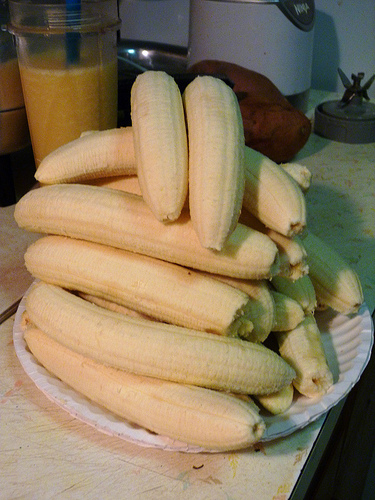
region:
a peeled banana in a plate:
[9, 190, 279, 279]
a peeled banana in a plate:
[26, 293, 298, 398]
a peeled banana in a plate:
[26, 329, 271, 458]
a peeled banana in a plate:
[22, 241, 258, 335]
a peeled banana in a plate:
[123, 66, 183, 222]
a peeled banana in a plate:
[177, 67, 253, 252]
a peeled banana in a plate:
[307, 225, 362, 321]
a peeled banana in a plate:
[285, 322, 355, 407]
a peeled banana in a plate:
[96, 163, 214, 216]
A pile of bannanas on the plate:
[30, 69, 364, 458]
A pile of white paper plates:
[305, 308, 374, 451]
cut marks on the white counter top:
[2, 423, 97, 499]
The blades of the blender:
[308, 56, 373, 144]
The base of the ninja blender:
[182, 0, 319, 88]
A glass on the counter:
[8, 0, 126, 187]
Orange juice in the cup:
[19, 0, 118, 130]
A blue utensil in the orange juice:
[61, 0, 85, 66]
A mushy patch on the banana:
[302, 321, 328, 371]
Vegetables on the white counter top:
[187, 49, 313, 161]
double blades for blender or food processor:
[315, 67, 374, 141]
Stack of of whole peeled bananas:
[21, 77, 361, 326]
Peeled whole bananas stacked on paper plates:
[21, 72, 374, 456]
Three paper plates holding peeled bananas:
[15, 265, 373, 452]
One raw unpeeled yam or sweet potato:
[185, 59, 311, 165]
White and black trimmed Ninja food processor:
[186, 1, 312, 111]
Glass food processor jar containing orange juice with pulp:
[5, 3, 121, 179]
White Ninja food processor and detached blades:
[187, 0, 373, 141]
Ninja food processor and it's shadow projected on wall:
[242, 0, 344, 98]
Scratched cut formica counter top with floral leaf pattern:
[52, 454, 282, 499]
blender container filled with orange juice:
[1, 0, 119, 181]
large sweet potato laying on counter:
[187, 57, 308, 162]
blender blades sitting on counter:
[316, 67, 373, 137]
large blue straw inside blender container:
[66, 0, 81, 64]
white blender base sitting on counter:
[188, 1, 312, 111]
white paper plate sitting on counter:
[16, 237, 372, 438]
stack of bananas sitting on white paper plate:
[17, 69, 363, 441]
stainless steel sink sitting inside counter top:
[0, 31, 191, 223]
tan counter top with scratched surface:
[0, 92, 372, 497]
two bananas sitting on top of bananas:
[126, 69, 248, 256]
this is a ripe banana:
[178, 74, 262, 260]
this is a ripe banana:
[131, 67, 186, 223]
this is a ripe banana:
[28, 332, 268, 460]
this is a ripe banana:
[24, 290, 299, 396]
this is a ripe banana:
[24, 246, 254, 340]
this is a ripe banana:
[11, 195, 293, 288]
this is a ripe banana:
[239, 150, 305, 246]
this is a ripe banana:
[314, 235, 373, 327]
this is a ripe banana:
[273, 305, 341, 400]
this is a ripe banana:
[253, 272, 279, 345]